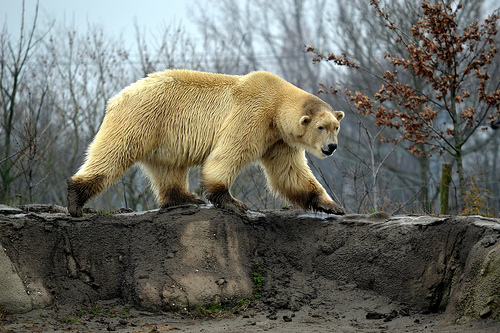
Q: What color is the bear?
A: White.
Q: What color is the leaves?
A: Brown.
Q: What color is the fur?
A: White.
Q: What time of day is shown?
A: In daytime.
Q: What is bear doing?
A: Prowling.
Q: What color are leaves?
A: Brown.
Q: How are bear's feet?
A: Muddy.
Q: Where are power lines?
A: In air.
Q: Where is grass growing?
A: In mud.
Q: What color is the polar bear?
A: White.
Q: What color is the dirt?
A: Gray.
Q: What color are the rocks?
A: Gray.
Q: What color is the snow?
A: White.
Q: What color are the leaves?
A: Brown.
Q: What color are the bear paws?
A: Brown.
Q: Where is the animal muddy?
A: His paws.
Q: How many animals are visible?
A: One.